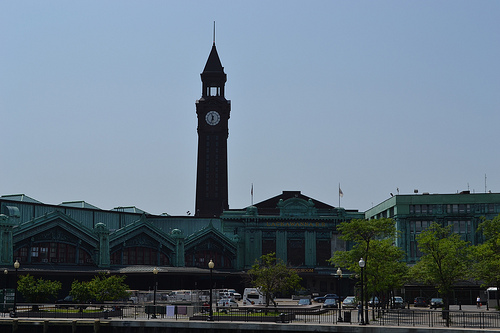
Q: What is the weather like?
A: It is clear.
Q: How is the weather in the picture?
A: It is clear.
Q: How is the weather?
A: It is clear.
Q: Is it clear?
A: Yes, it is clear.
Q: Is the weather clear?
A: Yes, it is clear.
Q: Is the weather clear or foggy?
A: It is clear.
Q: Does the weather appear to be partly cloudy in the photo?
A: No, it is clear.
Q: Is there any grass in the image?
A: Yes, there is grass.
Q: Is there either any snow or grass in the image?
A: Yes, there is grass.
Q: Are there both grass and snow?
A: No, there is grass but no snow.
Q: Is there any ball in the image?
A: No, there are no balls.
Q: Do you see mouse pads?
A: No, there are no mouse pads.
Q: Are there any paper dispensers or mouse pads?
A: No, there are no mouse pads or paper dispensers.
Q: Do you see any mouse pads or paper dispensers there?
A: No, there are no mouse pads or paper dispensers.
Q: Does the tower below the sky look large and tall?
A: Yes, the tower is large and tall.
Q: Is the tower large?
A: Yes, the tower is large.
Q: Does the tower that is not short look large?
A: Yes, the tower is large.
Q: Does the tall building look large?
A: Yes, the tower is large.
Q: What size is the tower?
A: The tower is large.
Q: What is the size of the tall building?
A: The tower is large.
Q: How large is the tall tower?
A: The tower is large.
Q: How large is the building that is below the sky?
A: The tower is large.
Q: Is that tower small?
A: No, the tower is large.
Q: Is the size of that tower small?
A: No, the tower is large.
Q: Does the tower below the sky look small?
A: No, the tower is large.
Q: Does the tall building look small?
A: No, the tower is large.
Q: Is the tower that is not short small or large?
A: The tower is large.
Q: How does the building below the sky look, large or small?
A: The tower is large.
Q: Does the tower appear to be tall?
A: Yes, the tower is tall.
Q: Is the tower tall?
A: Yes, the tower is tall.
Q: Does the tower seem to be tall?
A: Yes, the tower is tall.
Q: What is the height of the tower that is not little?
A: The tower is tall.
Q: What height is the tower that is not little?
A: The tower is tall.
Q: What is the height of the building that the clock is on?
A: The tower is tall.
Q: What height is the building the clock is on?
A: The tower is tall.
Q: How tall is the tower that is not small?
A: The tower is tall.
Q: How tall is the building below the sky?
A: The tower is tall.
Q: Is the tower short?
A: No, the tower is tall.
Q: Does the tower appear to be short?
A: No, the tower is tall.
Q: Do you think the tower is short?
A: No, the tower is tall.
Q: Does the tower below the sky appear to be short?
A: No, the tower is tall.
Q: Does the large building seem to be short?
A: No, the tower is tall.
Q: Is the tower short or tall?
A: The tower is tall.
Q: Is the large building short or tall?
A: The tower is tall.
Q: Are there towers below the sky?
A: Yes, there is a tower below the sky.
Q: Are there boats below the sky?
A: No, there is a tower below the sky.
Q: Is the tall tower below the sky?
A: Yes, the tower is below the sky.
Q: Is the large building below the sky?
A: Yes, the tower is below the sky.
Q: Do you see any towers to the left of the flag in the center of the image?
A: Yes, there is a tower to the left of the flag.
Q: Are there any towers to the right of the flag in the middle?
A: No, the tower is to the left of the flag.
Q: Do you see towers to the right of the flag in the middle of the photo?
A: No, the tower is to the left of the flag.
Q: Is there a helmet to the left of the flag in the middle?
A: No, there is a tower to the left of the flag.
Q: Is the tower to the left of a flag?
A: Yes, the tower is to the left of a flag.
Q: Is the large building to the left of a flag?
A: Yes, the tower is to the left of a flag.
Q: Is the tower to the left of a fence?
A: No, the tower is to the left of a flag.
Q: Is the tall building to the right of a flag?
A: No, the tower is to the left of a flag.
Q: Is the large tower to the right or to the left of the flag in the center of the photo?
A: The tower is to the left of the flag.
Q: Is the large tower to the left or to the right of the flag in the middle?
A: The tower is to the left of the flag.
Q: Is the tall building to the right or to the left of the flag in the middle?
A: The tower is to the left of the flag.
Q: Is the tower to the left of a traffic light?
A: No, the tower is to the left of the flag.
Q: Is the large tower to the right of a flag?
A: No, the tower is to the left of a flag.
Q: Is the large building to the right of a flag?
A: No, the tower is to the left of a flag.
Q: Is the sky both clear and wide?
A: Yes, the sky is clear and wide.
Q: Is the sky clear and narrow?
A: No, the sky is clear but wide.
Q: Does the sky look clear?
A: Yes, the sky is clear.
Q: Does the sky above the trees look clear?
A: Yes, the sky is clear.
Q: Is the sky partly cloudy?
A: No, the sky is clear.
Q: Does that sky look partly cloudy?
A: No, the sky is clear.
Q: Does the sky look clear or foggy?
A: The sky is clear.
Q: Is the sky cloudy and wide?
A: No, the sky is wide but clear.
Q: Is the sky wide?
A: Yes, the sky is wide.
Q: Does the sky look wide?
A: Yes, the sky is wide.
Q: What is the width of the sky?
A: The sky is wide.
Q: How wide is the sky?
A: The sky is wide.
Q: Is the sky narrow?
A: No, the sky is wide.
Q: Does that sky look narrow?
A: No, the sky is wide.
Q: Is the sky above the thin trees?
A: Yes, the sky is above the trees.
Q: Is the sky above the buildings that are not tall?
A: Yes, the sky is above the buildings.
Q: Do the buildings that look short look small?
A: Yes, the buildings are small.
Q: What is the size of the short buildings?
A: The buildings are small.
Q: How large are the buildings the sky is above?
A: The buildings are small.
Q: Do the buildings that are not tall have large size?
A: No, the buildings are small.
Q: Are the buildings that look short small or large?
A: The buildings are small.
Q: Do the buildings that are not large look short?
A: Yes, the buildings are short.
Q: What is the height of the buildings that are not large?
A: The buildings are short.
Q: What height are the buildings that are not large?
A: The buildings are short.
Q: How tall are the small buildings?
A: The buildings are short.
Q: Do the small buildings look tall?
A: No, the buildings are short.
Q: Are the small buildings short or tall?
A: The buildings are short.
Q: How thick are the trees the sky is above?
A: The trees are thin.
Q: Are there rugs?
A: No, there are no rugs.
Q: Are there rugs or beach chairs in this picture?
A: No, there are no rugs or beach chairs.